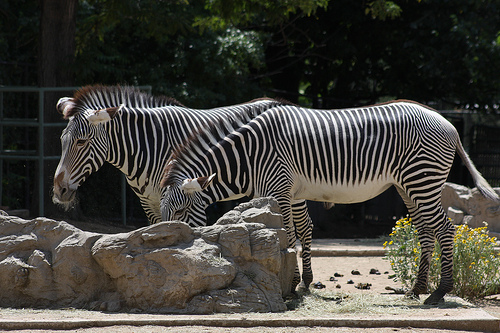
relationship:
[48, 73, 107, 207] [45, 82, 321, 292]
head of a zebra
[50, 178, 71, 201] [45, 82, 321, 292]
nose of a zebra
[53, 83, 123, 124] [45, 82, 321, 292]
ears of a zebra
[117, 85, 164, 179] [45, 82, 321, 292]
neck of a zebra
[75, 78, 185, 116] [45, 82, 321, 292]
main of a zebra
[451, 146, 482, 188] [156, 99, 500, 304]
tail of a zebra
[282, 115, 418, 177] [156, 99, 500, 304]
body of a zebra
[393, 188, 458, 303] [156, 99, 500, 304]
legs of a zebra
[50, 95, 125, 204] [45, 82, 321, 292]
head of a zebra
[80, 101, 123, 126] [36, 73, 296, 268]
ear of a zebra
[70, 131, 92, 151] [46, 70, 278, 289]
eye of a zebra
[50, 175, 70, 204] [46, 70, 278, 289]
nose of a zebra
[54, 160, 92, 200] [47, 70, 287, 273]
jaw of a zebra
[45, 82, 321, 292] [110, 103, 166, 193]
zebra has neck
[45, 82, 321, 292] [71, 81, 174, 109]
zebra has main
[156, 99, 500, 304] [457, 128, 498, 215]
zebra has tail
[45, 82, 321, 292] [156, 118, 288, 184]
zebra has body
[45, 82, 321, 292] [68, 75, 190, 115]
zebra has main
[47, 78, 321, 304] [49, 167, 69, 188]
zebra's face has nose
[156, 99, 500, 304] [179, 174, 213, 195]
zebra has ear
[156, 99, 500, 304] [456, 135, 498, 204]
zebra swinging tail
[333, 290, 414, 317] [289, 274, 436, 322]
patch on ground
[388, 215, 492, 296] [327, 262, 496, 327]
flowers are on ground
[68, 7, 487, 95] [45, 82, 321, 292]
trees behind zebra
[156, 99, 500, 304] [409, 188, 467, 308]
zebra has leg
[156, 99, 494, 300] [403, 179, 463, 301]
zebra has leg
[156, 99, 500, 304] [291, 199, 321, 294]
zebra has leg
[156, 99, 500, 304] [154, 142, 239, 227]
zebra has head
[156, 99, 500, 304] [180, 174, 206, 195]
zebra has ear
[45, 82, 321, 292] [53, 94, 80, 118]
zebra has ear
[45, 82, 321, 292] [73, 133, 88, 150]
zebra has eye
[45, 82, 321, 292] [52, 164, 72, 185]
zebra has nose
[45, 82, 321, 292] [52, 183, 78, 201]
zebra has mouth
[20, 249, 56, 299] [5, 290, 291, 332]
rock on ground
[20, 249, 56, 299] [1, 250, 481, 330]
rock on ground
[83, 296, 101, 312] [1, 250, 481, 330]
rock on ground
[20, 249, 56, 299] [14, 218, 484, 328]
rock on ground